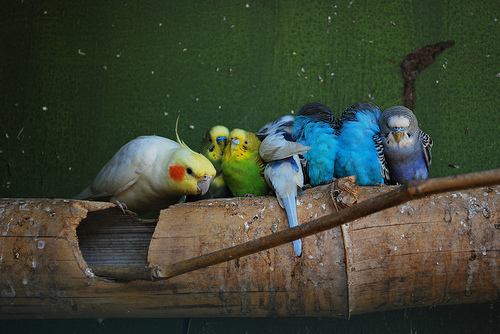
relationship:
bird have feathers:
[257, 110, 311, 259] [262, 117, 296, 257]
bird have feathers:
[288, 104, 340, 191] [304, 107, 332, 185]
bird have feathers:
[335, 101, 393, 187] [339, 100, 383, 189]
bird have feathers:
[380, 103, 427, 188] [389, 101, 431, 187]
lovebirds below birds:
[204, 120, 263, 195] [87, 93, 436, 257]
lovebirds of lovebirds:
[204, 120, 263, 195] [209, 120, 264, 188]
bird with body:
[380, 100, 434, 188] [387, 142, 435, 178]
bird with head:
[380, 100, 434, 188] [383, 104, 419, 142]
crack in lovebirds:
[130, 181, 420, 281] [204, 120, 263, 195]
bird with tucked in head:
[197, 125, 236, 197] [339, 107, 382, 129]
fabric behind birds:
[10, 11, 463, 184] [87, 93, 436, 257]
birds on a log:
[87, 93, 436, 257] [7, 190, 481, 304]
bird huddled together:
[197, 125, 236, 197] [204, 117, 260, 200]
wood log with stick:
[3, 175, 473, 325] [110, 171, 471, 272]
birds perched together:
[87, 93, 436, 257] [100, 105, 433, 225]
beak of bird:
[190, 175, 213, 195] [90, 124, 222, 206]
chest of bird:
[224, 159, 254, 179] [222, 125, 262, 194]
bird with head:
[73, 131, 234, 227] [165, 146, 216, 196]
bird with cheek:
[73, 131, 234, 227] [163, 160, 187, 186]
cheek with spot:
[163, 160, 187, 186] [168, 162, 183, 178]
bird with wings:
[335, 101, 393, 187] [338, 132, 388, 155]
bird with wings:
[288, 104, 340, 191] [310, 135, 336, 180]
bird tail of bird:
[279, 190, 302, 257] [257, 117, 306, 257]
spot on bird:
[166, 161, 189, 186] [74, 132, 228, 206]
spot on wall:
[401, 41, 459, 106] [3, 1, 495, 201]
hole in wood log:
[72, 201, 168, 281] [3, 175, 473, 325]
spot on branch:
[30, 231, 50, 260] [1, 177, 495, 329]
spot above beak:
[216, 132, 236, 149] [212, 132, 230, 153]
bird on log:
[219, 124, 266, 197] [0, 170, 497, 330]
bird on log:
[168, 116, 236, 197] [0, 170, 497, 330]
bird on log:
[259, 106, 319, 260] [0, 170, 497, 330]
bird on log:
[288, 104, 340, 191] [0, 170, 497, 330]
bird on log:
[326, 97, 393, 187] [0, 170, 497, 330]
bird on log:
[380, 103, 427, 188] [0, 170, 497, 330]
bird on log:
[335, 101, 393, 187] [0, 170, 497, 330]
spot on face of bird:
[166, 161, 189, 186] [83, 124, 224, 210]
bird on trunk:
[380, 103, 427, 188] [3, 169, 495, 332]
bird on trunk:
[335, 101, 393, 187] [3, 169, 495, 332]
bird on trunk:
[288, 104, 340, 191] [3, 169, 495, 332]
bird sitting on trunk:
[219, 124, 275, 195] [3, 169, 495, 332]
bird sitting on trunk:
[73, 131, 234, 227] [3, 169, 495, 332]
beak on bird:
[388, 127, 408, 146] [369, 104, 437, 185]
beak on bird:
[190, 175, 213, 195] [79, 125, 228, 228]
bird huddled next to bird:
[197, 125, 236, 197] [219, 124, 266, 197]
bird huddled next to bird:
[219, 124, 266, 197] [197, 125, 236, 197]